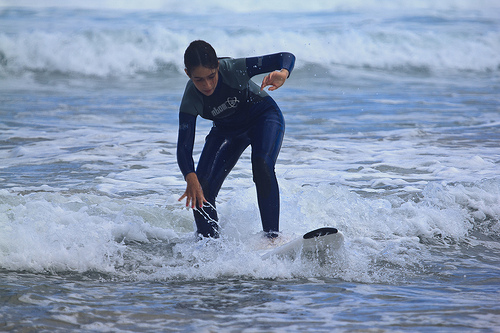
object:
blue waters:
[320, 82, 492, 146]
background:
[28, 23, 489, 277]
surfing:
[172, 30, 351, 287]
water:
[7, 181, 496, 304]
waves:
[5, 140, 498, 277]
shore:
[8, 283, 498, 333]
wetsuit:
[162, 68, 301, 245]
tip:
[300, 221, 345, 244]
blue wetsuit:
[169, 35, 299, 246]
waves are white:
[3, 32, 499, 82]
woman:
[160, 35, 300, 238]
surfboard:
[226, 226, 343, 266]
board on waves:
[245, 226, 355, 264]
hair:
[181, 39, 220, 71]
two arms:
[174, 50, 298, 181]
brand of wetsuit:
[210, 96, 242, 118]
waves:
[2, 22, 498, 84]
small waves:
[157, 237, 305, 281]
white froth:
[1, 203, 93, 264]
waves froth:
[0, 33, 80, 70]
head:
[183, 39, 221, 98]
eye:
[195, 78, 202, 82]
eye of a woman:
[209, 74, 216, 79]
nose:
[203, 80, 212, 88]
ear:
[184, 68, 191, 77]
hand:
[260, 68, 289, 92]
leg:
[252, 117, 283, 232]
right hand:
[175, 182, 208, 209]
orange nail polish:
[191, 206, 195, 208]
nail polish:
[186, 204, 189, 207]